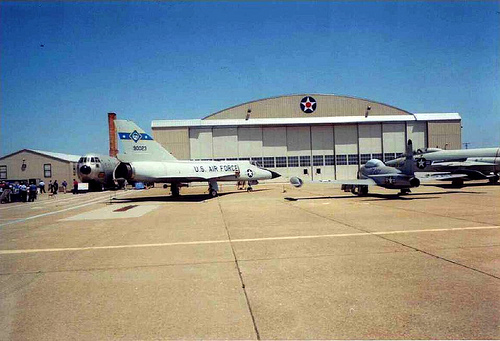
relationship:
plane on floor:
[91, 111, 294, 210] [0, 204, 500, 341]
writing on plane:
[186, 156, 256, 176] [67, 106, 303, 226]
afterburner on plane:
[107, 155, 139, 187] [91, 111, 294, 210]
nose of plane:
[268, 163, 291, 185] [89, 103, 311, 239]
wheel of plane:
[205, 180, 229, 205] [99, 107, 300, 212]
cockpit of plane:
[249, 160, 272, 179] [80, 93, 335, 237]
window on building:
[294, 158, 316, 182] [149, 74, 499, 244]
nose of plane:
[268, 169, 283, 180] [57, 106, 325, 221]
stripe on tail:
[89, 86, 144, 155] [60, 80, 208, 279]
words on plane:
[178, 135, 294, 204] [46, 89, 309, 249]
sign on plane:
[276, 78, 334, 128] [58, 105, 305, 235]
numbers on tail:
[91, 114, 125, 164] [70, 101, 187, 263]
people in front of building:
[34, 145, 109, 259] [15, 123, 112, 225]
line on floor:
[35, 206, 338, 286] [29, 151, 462, 323]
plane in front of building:
[40, 100, 311, 238] [113, 66, 474, 223]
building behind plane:
[165, 79, 432, 207] [109, 117, 283, 203]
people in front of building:
[12, 156, 102, 229] [21, 127, 108, 247]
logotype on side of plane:
[240, 166, 258, 186] [97, 101, 280, 192]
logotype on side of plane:
[417, 154, 439, 174] [386, 134, 499, 183]